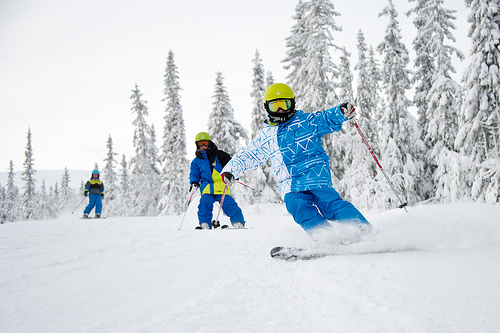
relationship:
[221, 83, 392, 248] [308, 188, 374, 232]
kid has leg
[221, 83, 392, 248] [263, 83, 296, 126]
kid wearing helmet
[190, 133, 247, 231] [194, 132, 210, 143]
child wearing helmet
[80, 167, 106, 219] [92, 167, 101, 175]
boy wearing helmet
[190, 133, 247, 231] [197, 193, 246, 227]
child wearing pants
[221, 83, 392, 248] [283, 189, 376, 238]
kid wearing pants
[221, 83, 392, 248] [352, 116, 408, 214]
kid has ski pole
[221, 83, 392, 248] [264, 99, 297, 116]
kid wearing goggles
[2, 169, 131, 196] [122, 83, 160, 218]
hill behind tree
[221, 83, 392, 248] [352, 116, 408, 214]
kid holding ski pole